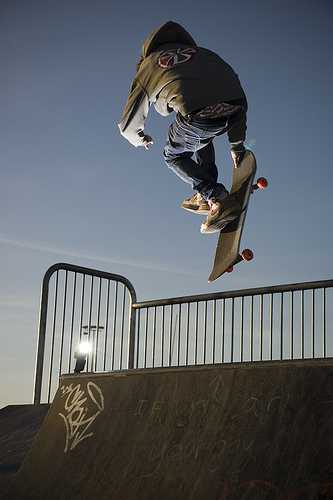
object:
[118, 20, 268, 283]
man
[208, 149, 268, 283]
skateboard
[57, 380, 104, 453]
graffiti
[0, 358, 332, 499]
ramp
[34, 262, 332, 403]
fence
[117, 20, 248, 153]
hoodie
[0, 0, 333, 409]
sky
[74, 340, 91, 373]
light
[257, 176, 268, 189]
wheels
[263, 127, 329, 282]
air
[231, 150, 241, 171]
hand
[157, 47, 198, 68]
graphic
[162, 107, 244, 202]
jeans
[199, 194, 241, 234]
shoes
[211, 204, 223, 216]
nike logo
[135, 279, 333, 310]
pole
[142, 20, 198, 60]
hood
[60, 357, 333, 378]
top